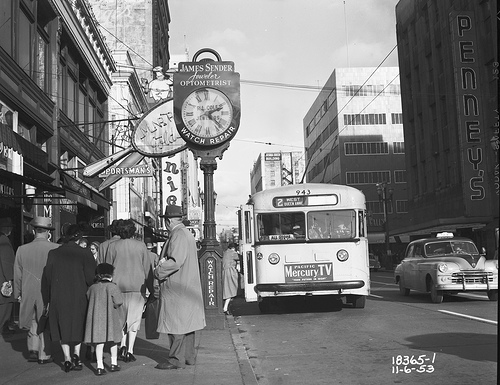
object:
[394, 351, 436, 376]
photo date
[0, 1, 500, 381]
photo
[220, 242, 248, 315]
woman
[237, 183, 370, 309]
bus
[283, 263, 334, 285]
mercury tv ad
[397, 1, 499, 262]
building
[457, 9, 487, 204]
penney's sign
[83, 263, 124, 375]
child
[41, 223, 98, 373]
woman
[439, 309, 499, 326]
street line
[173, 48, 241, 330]
clock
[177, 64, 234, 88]
ad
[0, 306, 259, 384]
sidewalk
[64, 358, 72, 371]
black shoes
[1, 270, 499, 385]
street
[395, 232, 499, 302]
taxi cab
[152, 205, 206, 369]
man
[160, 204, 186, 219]
hat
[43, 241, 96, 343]
coat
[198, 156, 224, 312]
pole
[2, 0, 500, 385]
city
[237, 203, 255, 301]
doors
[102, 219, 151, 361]
woman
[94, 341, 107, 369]
white tights